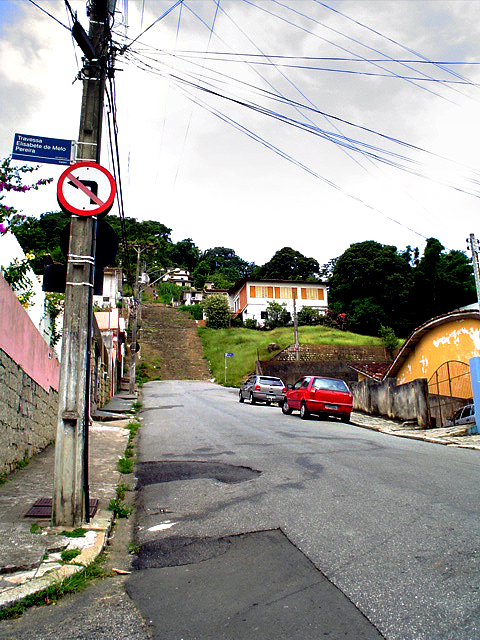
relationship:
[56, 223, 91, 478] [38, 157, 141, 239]
sign on pole